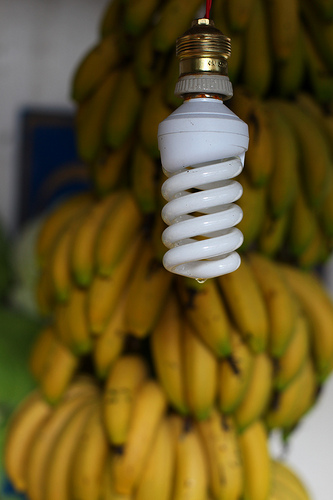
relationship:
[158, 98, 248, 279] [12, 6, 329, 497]
bulb hanging in front of some bananas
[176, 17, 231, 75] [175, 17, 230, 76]
gold metal on light socket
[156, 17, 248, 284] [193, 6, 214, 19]
light on wire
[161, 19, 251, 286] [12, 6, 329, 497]
light in front of bananas